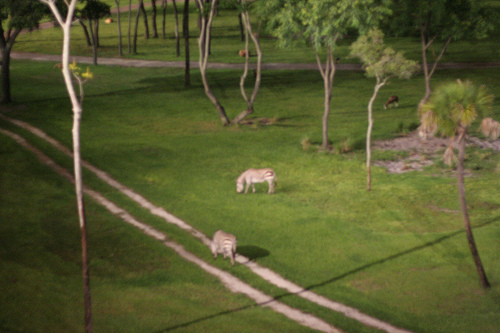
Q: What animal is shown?
A: Zebra.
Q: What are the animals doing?
A: Eating.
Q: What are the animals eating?
A: Grass.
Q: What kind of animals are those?
A: Those are zebras.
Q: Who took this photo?
A: Jackson Mingus.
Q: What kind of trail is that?
A: That is a gravel trail.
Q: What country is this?
A: South Africa.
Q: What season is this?
A: Summer.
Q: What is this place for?
A: It is a safari park.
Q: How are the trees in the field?
A: They are thin.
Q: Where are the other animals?
A: On the background.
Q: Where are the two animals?
A: On the grass.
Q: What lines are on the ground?
A: Two parallel white lines.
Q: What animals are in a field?
A: Two zebras.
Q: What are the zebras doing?
A: Grazing on grass.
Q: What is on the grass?
A: Zebras.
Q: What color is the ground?
A: Green.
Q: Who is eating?
A: The zebra.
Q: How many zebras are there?
A: Two.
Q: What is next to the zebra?
A: Trees.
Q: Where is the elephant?
A: Not in the photo.